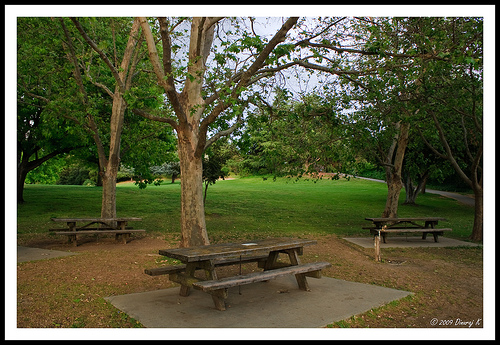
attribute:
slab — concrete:
[340, 229, 484, 254]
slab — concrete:
[99, 263, 418, 328]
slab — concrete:
[15, 242, 80, 269]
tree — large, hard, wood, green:
[53, 14, 190, 235]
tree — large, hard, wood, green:
[19, 18, 165, 209]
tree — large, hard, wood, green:
[70, 18, 450, 261]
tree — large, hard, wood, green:
[358, 18, 483, 249]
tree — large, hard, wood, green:
[323, 18, 433, 226]